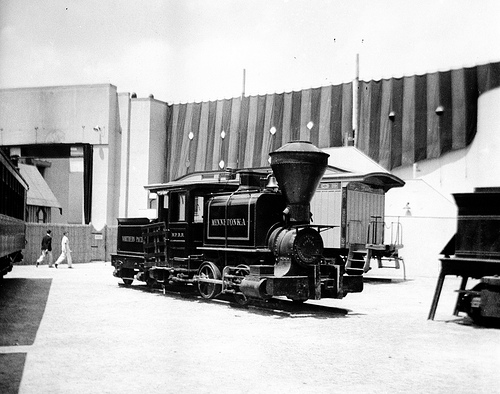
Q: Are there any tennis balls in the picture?
A: No, there are no tennis balls.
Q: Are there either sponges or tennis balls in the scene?
A: No, there are no tennis balls or sponges.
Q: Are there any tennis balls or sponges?
A: No, there are no tennis balls or sponges.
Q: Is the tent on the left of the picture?
A: Yes, the tent is on the left of the image.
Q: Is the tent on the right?
A: No, the tent is on the left of the image.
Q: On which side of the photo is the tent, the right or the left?
A: The tent is on the left of the image.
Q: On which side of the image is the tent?
A: The tent is on the left of the image.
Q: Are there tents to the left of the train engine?
A: Yes, there is a tent to the left of the train engine.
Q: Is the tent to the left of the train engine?
A: Yes, the tent is to the left of the train engine.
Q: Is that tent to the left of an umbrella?
A: No, the tent is to the left of the train engine.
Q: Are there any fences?
A: Yes, there is a fence.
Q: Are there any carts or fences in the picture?
A: Yes, there is a fence.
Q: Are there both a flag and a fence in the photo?
A: No, there is a fence but no flags.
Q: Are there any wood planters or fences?
A: Yes, there is a wood fence.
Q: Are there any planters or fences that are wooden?
A: Yes, the fence is wooden.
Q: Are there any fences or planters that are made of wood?
A: Yes, the fence is made of wood.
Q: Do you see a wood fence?
A: Yes, there is a wood fence.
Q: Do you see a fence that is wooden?
A: Yes, there is a fence that is wooden.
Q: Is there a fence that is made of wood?
A: Yes, there is a fence that is made of wood.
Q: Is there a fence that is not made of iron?
A: Yes, there is a fence that is made of wood.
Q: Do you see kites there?
A: No, there are no kites.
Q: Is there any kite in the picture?
A: No, there are no kites.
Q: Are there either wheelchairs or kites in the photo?
A: No, there are no kites or wheelchairs.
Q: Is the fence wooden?
A: Yes, the fence is wooden.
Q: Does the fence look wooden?
A: Yes, the fence is wooden.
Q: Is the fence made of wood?
A: Yes, the fence is made of wood.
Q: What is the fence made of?
A: The fence is made of wood.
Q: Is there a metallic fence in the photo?
A: No, there is a fence but it is wooden.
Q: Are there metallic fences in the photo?
A: No, there is a fence but it is wooden.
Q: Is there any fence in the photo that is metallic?
A: No, there is a fence but it is wooden.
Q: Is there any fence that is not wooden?
A: No, there is a fence but it is wooden.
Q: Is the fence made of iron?
A: No, the fence is made of wood.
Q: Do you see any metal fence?
A: No, there is a fence but it is made of wood.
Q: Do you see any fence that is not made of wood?
A: No, there is a fence but it is made of wood.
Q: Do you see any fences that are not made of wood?
A: No, there is a fence but it is made of wood.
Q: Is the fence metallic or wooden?
A: The fence is wooden.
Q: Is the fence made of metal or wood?
A: The fence is made of wood.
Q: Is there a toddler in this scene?
A: No, there are no toddlers.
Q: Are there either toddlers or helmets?
A: No, there are no toddlers or helmets.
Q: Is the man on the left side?
A: Yes, the man is on the left of the image.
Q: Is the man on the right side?
A: No, the man is on the left of the image.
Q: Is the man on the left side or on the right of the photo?
A: The man is on the left of the image.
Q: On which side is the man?
A: The man is on the left of the image.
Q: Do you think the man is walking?
A: Yes, the man is walking.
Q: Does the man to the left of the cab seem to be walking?
A: Yes, the man is walking.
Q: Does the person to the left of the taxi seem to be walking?
A: Yes, the man is walking.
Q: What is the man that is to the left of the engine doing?
A: The man is walking.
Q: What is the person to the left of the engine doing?
A: The man is walking.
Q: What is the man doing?
A: The man is walking.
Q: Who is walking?
A: The man is walking.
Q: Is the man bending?
A: No, the man is walking.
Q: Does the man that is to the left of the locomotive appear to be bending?
A: No, the man is walking.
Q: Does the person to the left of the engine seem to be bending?
A: No, the man is walking.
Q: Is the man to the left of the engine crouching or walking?
A: The man is walking.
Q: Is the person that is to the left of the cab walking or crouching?
A: The man is walking.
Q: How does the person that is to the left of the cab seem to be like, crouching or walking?
A: The man is walking.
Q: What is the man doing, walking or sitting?
A: The man is walking.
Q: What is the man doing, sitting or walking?
A: The man is walking.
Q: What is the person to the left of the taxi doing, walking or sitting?
A: The man is walking.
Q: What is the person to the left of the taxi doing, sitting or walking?
A: The man is walking.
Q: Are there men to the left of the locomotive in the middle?
A: Yes, there is a man to the left of the locomotive.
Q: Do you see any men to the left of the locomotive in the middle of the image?
A: Yes, there is a man to the left of the locomotive.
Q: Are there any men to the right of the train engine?
A: No, the man is to the left of the train engine.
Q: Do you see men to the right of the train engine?
A: No, the man is to the left of the train engine.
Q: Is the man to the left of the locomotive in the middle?
A: Yes, the man is to the left of the engine.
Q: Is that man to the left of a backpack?
A: No, the man is to the left of the engine.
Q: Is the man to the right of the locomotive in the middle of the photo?
A: No, the man is to the left of the engine.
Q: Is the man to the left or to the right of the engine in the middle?
A: The man is to the left of the engine.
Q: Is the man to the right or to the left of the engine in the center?
A: The man is to the left of the engine.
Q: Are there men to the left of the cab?
A: Yes, there is a man to the left of the cab.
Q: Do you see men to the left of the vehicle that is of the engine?
A: Yes, there is a man to the left of the cab.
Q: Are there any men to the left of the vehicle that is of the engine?
A: Yes, there is a man to the left of the cab.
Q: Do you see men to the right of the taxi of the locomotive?
A: No, the man is to the left of the taxi.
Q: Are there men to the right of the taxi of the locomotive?
A: No, the man is to the left of the taxi.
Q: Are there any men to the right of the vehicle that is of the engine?
A: No, the man is to the left of the taxi.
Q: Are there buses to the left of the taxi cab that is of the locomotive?
A: No, there is a man to the left of the taxi.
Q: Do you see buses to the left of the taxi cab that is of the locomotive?
A: No, there is a man to the left of the taxi.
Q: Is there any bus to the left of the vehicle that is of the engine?
A: No, there is a man to the left of the taxi.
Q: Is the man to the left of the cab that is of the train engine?
A: Yes, the man is to the left of the taxi cab.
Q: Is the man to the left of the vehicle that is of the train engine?
A: Yes, the man is to the left of the taxi cab.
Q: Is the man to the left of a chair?
A: No, the man is to the left of the taxi cab.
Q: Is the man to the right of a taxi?
A: No, the man is to the left of a taxi.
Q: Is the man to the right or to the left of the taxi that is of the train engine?
A: The man is to the left of the taxi.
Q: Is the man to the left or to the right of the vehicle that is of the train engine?
A: The man is to the left of the taxi.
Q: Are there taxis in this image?
A: Yes, there is a taxi.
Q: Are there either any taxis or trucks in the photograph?
A: Yes, there is a taxi.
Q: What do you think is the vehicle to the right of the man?
A: The vehicle is a taxi.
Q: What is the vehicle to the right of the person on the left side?
A: The vehicle is a taxi.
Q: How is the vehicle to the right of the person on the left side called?
A: The vehicle is a taxi.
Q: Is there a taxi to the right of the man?
A: Yes, there is a taxi to the right of the man.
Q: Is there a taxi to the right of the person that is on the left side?
A: Yes, there is a taxi to the right of the man.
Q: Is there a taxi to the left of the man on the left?
A: No, the taxi is to the right of the man.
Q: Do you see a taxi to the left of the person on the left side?
A: No, the taxi is to the right of the man.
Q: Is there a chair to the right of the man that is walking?
A: No, there is a taxi to the right of the man.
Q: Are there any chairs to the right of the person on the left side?
A: No, there is a taxi to the right of the man.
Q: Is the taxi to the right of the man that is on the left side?
A: Yes, the taxi is to the right of the man.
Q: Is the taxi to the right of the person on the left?
A: Yes, the taxi is to the right of the man.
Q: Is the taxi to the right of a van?
A: No, the taxi is to the right of the man.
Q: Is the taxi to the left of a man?
A: No, the taxi is to the right of a man.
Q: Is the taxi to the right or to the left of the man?
A: The taxi is to the right of the man.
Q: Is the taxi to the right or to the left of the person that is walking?
A: The taxi is to the right of the man.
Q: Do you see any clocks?
A: No, there are no clocks.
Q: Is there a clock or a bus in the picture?
A: No, there are no clocks or buses.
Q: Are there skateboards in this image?
A: No, there are no skateboards.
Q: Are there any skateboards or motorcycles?
A: No, there are no skateboards or motorcycles.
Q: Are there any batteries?
A: No, there are no batteries.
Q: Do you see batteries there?
A: No, there are no batteries.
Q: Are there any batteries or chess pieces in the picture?
A: No, there are no batteries or chess pieces.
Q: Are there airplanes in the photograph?
A: No, there are no airplanes.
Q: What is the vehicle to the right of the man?
A: The vehicle is a locomotive.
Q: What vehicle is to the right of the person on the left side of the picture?
A: The vehicle is a locomotive.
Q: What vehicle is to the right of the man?
A: The vehicle is a locomotive.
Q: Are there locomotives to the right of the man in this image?
A: Yes, there is a locomotive to the right of the man.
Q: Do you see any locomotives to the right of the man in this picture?
A: Yes, there is a locomotive to the right of the man.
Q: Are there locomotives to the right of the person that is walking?
A: Yes, there is a locomotive to the right of the man.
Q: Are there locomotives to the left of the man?
A: No, the locomotive is to the right of the man.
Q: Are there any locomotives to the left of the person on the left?
A: No, the locomotive is to the right of the man.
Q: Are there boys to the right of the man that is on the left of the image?
A: No, there is a locomotive to the right of the man.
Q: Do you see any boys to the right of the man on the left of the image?
A: No, there is a locomotive to the right of the man.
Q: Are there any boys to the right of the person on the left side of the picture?
A: No, there is a locomotive to the right of the man.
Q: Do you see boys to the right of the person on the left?
A: No, there is a locomotive to the right of the man.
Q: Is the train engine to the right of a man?
A: Yes, the train engine is to the right of a man.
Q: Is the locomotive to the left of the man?
A: No, the locomotive is to the right of the man.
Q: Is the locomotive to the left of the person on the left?
A: No, the locomotive is to the right of the man.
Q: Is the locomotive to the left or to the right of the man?
A: The locomotive is to the right of the man.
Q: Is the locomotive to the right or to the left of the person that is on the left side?
A: The locomotive is to the right of the man.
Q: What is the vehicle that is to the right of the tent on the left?
A: The vehicle is a locomotive.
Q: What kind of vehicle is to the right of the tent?
A: The vehicle is a locomotive.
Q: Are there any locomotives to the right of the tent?
A: Yes, there is a locomotive to the right of the tent.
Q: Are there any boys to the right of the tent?
A: No, there is a locomotive to the right of the tent.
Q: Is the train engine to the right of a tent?
A: Yes, the train engine is to the right of a tent.